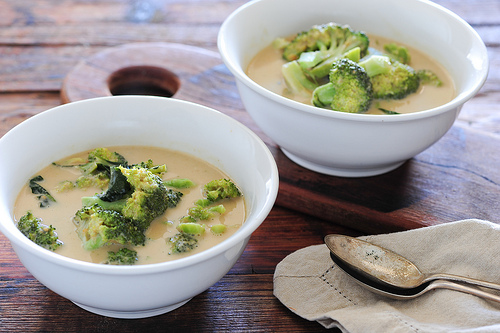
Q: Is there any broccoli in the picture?
A: Yes, there is broccoli.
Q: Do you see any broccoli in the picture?
A: Yes, there is broccoli.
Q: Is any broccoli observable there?
A: Yes, there is broccoli.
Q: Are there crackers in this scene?
A: No, there are no crackers.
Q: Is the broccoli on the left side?
A: Yes, the broccoli is on the left of the image.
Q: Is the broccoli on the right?
A: No, the broccoli is on the left of the image.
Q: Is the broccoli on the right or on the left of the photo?
A: The broccoli is on the left of the image.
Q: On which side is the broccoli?
A: The broccoli is on the left of the image.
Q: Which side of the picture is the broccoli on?
A: The broccoli is on the left of the image.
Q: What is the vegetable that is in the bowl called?
A: The vegetable is broccoli.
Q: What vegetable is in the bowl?
A: The vegetable is broccoli.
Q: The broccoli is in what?
A: The broccoli is in the bowl.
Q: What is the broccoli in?
A: The broccoli is in the bowl.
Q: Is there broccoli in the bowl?
A: Yes, there is broccoli in the bowl.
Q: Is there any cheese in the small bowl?
A: No, there is broccoli in the bowl.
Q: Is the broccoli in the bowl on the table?
A: Yes, the broccoli is in the bowl.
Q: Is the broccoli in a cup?
A: No, the broccoli is in the bowl.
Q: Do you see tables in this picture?
A: Yes, there is a table.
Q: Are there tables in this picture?
A: Yes, there is a table.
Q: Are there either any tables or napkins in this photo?
A: Yes, there is a table.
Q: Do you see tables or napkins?
A: Yes, there is a table.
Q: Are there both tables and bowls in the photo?
A: Yes, there are both a table and a bowl.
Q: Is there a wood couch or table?
A: Yes, there is a wood table.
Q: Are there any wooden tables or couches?
A: Yes, there is a wood table.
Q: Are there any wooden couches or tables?
A: Yes, there is a wood table.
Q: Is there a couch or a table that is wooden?
A: Yes, the table is wooden.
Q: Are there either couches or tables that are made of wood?
A: Yes, the table is made of wood.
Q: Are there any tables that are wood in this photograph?
A: Yes, there is a wood table.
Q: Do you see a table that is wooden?
A: Yes, there is a table that is wooden.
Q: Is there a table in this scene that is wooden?
A: Yes, there is a table that is wooden.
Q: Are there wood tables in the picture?
A: Yes, there is a table that is made of wood.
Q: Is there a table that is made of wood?
A: Yes, there is a table that is made of wood.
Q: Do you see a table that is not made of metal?
A: Yes, there is a table that is made of wood.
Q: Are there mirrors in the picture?
A: No, there are no mirrors.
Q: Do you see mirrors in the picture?
A: No, there are no mirrors.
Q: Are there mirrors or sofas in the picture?
A: No, there are no mirrors or sofas.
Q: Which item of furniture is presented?
A: The piece of furniture is a table.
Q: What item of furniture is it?
A: The piece of furniture is a table.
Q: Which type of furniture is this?
A: That is a table.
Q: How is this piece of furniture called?
A: That is a table.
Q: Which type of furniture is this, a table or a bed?
A: That is a table.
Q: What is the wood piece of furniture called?
A: The piece of furniture is a table.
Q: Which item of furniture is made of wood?
A: The piece of furniture is a table.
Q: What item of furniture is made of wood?
A: The piece of furniture is a table.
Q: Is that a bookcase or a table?
A: That is a table.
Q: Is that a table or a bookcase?
A: That is a table.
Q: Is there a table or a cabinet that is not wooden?
A: No, there is a table but it is wooden.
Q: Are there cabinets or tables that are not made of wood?
A: No, there is a table but it is made of wood.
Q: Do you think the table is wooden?
A: Yes, the table is wooden.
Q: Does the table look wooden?
A: Yes, the table is wooden.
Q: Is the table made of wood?
A: Yes, the table is made of wood.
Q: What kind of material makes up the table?
A: The table is made of wood.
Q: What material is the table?
A: The table is made of wood.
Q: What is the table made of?
A: The table is made of wood.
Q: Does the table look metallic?
A: No, the table is wooden.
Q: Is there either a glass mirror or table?
A: No, there is a table but it is wooden.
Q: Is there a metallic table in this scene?
A: No, there is a table but it is wooden.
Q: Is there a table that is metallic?
A: No, there is a table but it is wooden.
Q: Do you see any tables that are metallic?
A: No, there is a table but it is wooden.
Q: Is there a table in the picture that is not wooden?
A: No, there is a table but it is wooden.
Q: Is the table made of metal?
A: No, the table is made of wood.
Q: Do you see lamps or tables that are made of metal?
A: No, there is a table but it is made of wood.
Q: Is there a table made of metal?
A: No, there is a table but it is made of wood.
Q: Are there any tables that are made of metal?
A: No, there is a table but it is made of wood.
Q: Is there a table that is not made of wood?
A: No, there is a table but it is made of wood.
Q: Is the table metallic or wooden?
A: The table is wooden.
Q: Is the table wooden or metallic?
A: The table is wooden.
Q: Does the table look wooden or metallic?
A: The table is wooden.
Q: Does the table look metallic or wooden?
A: The table is wooden.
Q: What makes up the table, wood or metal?
A: The table is made of wood.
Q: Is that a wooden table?
A: Yes, that is a wooden table.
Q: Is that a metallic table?
A: No, that is a wooden table.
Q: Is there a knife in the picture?
A: No, there are no knives.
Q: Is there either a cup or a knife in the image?
A: No, there are no knives or cups.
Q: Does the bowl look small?
A: Yes, the bowl is small.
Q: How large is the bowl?
A: The bowl is small.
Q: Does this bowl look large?
A: No, the bowl is small.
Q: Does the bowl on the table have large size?
A: No, the bowl is small.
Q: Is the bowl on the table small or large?
A: The bowl is small.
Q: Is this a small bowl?
A: Yes, this is a small bowl.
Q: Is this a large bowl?
A: No, this is a small bowl.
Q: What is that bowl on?
A: The bowl is on the table.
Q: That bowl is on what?
A: The bowl is on the table.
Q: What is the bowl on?
A: The bowl is on the table.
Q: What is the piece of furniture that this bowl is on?
A: The piece of furniture is a table.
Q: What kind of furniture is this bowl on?
A: The bowl is on the table.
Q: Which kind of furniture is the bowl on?
A: The bowl is on the table.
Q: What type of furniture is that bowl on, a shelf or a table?
A: The bowl is on a table.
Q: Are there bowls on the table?
A: Yes, there is a bowl on the table.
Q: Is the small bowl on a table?
A: Yes, the bowl is on a table.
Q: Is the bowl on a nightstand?
A: No, the bowl is on a table.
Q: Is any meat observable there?
A: No, there is no meat.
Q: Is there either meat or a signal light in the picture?
A: No, there are no meat or traffic lights.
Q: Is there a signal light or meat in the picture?
A: No, there are no meat or traffic lights.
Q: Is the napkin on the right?
A: Yes, the napkin is on the right of the image.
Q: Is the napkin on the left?
A: No, the napkin is on the right of the image.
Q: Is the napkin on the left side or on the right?
A: The napkin is on the right of the image.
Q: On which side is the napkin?
A: The napkin is on the right of the image.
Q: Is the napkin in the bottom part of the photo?
A: Yes, the napkin is in the bottom of the image.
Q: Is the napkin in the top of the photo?
A: No, the napkin is in the bottom of the image.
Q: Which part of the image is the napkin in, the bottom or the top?
A: The napkin is in the bottom of the image.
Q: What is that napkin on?
A: The napkin is on the table.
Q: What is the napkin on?
A: The napkin is on the table.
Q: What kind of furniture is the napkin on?
A: The napkin is on the table.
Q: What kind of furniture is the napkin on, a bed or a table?
A: The napkin is on a table.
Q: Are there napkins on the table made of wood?
A: Yes, there is a napkin on the table.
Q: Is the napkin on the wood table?
A: Yes, the napkin is on the table.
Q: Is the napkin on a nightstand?
A: No, the napkin is on the table.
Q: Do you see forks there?
A: No, there are no forks.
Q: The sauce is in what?
A: The sauce is in the bowl.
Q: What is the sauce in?
A: The sauce is in the bowl.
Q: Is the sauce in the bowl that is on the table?
A: Yes, the sauce is in the bowl.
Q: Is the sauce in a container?
A: No, the sauce is in the bowl.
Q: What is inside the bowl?
A: The sauce is inside the bowl.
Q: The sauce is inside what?
A: The sauce is inside the bowl.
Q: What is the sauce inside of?
A: The sauce is inside the bowl.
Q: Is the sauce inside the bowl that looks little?
A: Yes, the sauce is inside the bowl.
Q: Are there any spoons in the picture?
A: Yes, there is a spoon.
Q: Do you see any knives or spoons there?
A: Yes, there is a spoon.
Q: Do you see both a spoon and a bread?
A: No, there is a spoon but no breads.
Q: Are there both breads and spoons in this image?
A: No, there is a spoon but no breads.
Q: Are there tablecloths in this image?
A: No, there are no tablecloths.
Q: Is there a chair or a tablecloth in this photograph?
A: No, there are no tablecloths or chairs.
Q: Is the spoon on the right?
A: Yes, the spoon is on the right of the image.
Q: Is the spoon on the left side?
A: No, the spoon is on the right of the image.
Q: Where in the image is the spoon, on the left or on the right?
A: The spoon is on the right of the image.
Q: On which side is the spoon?
A: The spoon is on the right of the image.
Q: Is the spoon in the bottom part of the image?
A: Yes, the spoon is in the bottom of the image.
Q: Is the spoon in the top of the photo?
A: No, the spoon is in the bottom of the image.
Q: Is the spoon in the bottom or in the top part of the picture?
A: The spoon is in the bottom of the image.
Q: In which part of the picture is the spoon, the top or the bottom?
A: The spoon is in the bottom of the image.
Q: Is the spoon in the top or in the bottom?
A: The spoon is in the bottom of the image.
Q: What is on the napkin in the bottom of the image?
A: The spoon is on the napkin.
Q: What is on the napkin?
A: The spoon is on the napkin.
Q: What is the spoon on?
A: The spoon is on the napkin.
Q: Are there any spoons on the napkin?
A: Yes, there is a spoon on the napkin.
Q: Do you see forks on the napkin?
A: No, there is a spoon on the napkin.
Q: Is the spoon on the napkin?
A: Yes, the spoon is on the napkin.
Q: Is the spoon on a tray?
A: No, the spoon is on the napkin.